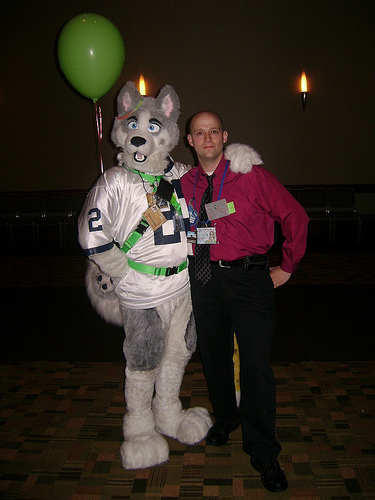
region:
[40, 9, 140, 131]
GREEN RUBBER BALLOON IN AIR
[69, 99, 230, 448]
MAN IN LARGE DOG COSTUME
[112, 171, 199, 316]
WHITE JERSEY ON DOG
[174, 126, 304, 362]
MAN IN RED COLLARED SHIRT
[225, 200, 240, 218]
GREEN STICKER ON MAN'S SHIRT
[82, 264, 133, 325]
SMALL DOG BEHIND COSTUME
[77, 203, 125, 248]
NUMBER 2 ON MAN'S JERSEY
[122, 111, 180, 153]
BLUE EYES ON COSTUME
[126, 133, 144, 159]
OPEN MOUTH ON DOG COSTUME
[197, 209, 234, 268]
TAG HANGING ON MAN'S SHIRT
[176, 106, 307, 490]
Man wearing a red shirt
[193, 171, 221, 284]
Tie around man's neck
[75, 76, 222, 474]
Person wearing a wolf costume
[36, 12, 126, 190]
Balloon on side of person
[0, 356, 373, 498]
Checkered rug covering floor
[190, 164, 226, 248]
Id card hanging from man's neck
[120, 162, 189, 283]
Green straps around person in costume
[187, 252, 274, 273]
Black belt on man's waist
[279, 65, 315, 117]
Light hanging on wall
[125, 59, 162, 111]
Light behind the person in wolf suit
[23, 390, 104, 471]
The carpet is on the floor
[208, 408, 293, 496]
The feet on the man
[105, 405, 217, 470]
The feet on the wolf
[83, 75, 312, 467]
The man is standing with a mascot wolf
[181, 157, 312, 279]
The man is wearing a burgundy shirt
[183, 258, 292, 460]
The man is wearing black pants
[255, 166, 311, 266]
The arm of the man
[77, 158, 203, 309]
The wolf has on a jersey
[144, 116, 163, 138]
The eye of the wolf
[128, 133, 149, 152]
The nose of the wolf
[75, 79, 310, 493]
a man and a mascot pose for picture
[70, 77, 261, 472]
a mascot wearing a white jersey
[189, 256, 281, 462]
a man wearing black pants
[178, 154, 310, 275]
a man wearing a red shirt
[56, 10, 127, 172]
a green balloon behind mascot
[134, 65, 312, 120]
two light fixtures attached to wall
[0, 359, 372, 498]
a multi colored carpet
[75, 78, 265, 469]
a gray and white mascot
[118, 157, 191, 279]
a mascot wearing a green harness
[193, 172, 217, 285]
a man wearing a black tie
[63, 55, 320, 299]
a man with a mascot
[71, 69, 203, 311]
this mascot is a coyote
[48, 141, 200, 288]
the mascot is wearing a blue jersey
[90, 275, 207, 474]
he has white legs with gray spots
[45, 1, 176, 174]
a green balloon behind the mascot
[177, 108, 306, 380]
the man is wearing a maroon shirt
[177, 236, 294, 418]
he has on black pants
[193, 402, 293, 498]
he is wearing black shoes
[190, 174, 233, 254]
he is an employee at a company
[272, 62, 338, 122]
a light on the wall